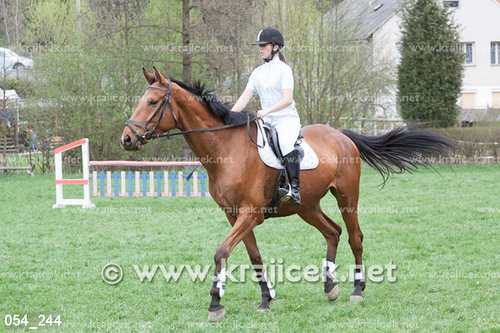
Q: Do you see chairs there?
A: No, there are no chairs.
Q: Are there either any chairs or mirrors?
A: No, there are no chairs or mirrors.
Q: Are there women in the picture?
A: Yes, there is a woman.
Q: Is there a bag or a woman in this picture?
A: Yes, there is a woman.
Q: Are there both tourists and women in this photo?
A: No, there is a woman but no tourists.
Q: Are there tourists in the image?
A: No, there are no tourists.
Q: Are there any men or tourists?
A: No, there are no tourists or men.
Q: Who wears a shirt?
A: The woman wears a shirt.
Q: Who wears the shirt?
A: The woman wears a shirt.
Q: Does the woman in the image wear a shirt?
A: Yes, the woman wears a shirt.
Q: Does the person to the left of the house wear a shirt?
A: Yes, the woman wears a shirt.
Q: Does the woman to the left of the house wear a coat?
A: No, the woman wears a shirt.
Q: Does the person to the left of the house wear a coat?
A: No, the woman wears a shirt.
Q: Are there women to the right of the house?
A: No, the woman is to the left of the house.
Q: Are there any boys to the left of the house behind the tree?
A: No, there is a woman to the left of the house.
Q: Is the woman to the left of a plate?
A: No, the woman is to the left of the house.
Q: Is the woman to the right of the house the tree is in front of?
A: No, the woman is to the left of the house.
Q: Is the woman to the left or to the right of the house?
A: The woman is to the left of the house.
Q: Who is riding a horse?
A: The woman is riding a horse.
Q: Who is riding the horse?
A: The woman is riding a horse.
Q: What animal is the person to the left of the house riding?
A: The woman is riding a horse.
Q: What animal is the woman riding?
A: The woman is riding a horse.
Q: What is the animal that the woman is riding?
A: The animal is a horse.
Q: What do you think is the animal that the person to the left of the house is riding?
A: The animal is a horse.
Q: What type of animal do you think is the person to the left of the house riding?
A: The woman is riding a horse.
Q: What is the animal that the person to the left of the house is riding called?
A: The animal is a horse.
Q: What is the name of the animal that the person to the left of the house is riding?
A: The animal is a horse.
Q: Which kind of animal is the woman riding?
A: The woman is riding a horse.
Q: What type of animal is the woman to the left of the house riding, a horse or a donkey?
A: The woman is riding a horse.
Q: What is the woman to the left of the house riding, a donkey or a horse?
A: The woman is riding a horse.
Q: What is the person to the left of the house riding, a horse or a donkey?
A: The woman is riding a horse.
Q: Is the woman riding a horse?
A: Yes, the woman is riding a horse.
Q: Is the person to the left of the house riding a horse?
A: Yes, the woman is riding a horse.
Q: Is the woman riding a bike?
A: No, the woman is riding a horse.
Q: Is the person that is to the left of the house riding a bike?
A: No, the woman is riding a horse.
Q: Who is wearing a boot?
A: The woman is wearing a boot.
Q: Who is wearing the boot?
A: The woman is wearing a boot.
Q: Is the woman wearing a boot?
A: Yes, the woman is wearing a boot.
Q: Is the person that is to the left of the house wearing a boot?
A: Yes, the woman is wearing a boot.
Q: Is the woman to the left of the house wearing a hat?
A: No, the woman is wearing a boot.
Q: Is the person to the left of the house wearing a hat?
A: No, the woman is wearing a boot.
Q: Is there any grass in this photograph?
A: Yes, there is grass.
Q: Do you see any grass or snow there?
A: Yes, there is grass.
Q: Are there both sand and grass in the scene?
A: No, there is grass but no sand.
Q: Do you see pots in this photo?
A: No, there are no pots.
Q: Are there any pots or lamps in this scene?
A: No, there are no pots or lamps.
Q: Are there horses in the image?
A: Yes, there is a horse.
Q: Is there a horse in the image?
A: Yes, there is a horse.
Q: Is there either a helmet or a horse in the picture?
A: Yes, there is a horse.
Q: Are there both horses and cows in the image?
A: No, there is a horse but no cows.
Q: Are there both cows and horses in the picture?
A: No, there is a horse but no cows.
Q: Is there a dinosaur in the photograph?
A: No, there are no dinosaurs.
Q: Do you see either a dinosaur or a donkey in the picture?
A: No, there are no dinosaurs or donkeys.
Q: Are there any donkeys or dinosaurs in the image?
A: No, there are no dinosaurs or donkeys.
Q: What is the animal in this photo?
A: The animal is a horse.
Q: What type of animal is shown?
A: The animal is a horse.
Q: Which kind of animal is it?
A: The animal is a horse.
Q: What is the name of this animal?
A: This is a horse.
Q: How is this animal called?
A: This is a horse.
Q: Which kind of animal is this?
A: This is a horse.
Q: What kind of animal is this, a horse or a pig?
A: This is a horse.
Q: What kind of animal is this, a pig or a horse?
A: This is a horse.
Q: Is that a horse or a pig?
A: That is a horse.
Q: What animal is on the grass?
A: The horse is on the grass.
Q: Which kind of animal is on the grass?
A: The animal is a horse.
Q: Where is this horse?
A: The horse is on the grass.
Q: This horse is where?
A: The horse is on the grass.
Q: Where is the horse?
A: The horse is on the grass.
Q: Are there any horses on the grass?
A: Yes, there is a horse on the grass.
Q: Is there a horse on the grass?
A: Yes, there is a horse on the grass.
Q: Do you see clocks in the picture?
A: No, there are no clocks.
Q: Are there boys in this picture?
A: No, there are no boys.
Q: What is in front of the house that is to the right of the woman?
A: The tree is in front of the house.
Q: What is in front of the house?
A: The tree is in front of the house.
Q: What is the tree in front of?
A: The tree is in front of the house.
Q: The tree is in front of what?
A: The tree is in front of the house.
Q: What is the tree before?
A: The tree is in front of the house.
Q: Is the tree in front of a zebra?
A: No, the tree is in front of the house.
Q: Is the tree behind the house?
A: No, the tree is in front of the house.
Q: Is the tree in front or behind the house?
A: The tree is in front of the house.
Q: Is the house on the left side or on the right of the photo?
A: The house is on the right of the image.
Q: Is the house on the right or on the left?
A: The house is on the right of the image.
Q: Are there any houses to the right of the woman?
A: Yes, there is a house to the right of the woman.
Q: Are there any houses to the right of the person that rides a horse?
A: Yes, there is a house to the right of the woman.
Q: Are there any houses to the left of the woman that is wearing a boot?
A: No, the house is to the right of the woman.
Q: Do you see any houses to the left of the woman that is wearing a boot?
A: No, the house is to the right of the woman.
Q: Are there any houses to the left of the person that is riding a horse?
A: No, the house is to the right of the woman.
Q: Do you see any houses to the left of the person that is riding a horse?
A: No, the house is to the right of the woman.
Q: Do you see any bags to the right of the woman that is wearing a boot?
A: No, there is a house to the right of the woman.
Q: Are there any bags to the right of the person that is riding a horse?
A: No, there is a house to the right of the woman.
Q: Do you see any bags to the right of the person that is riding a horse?
A: No, there is a house to the right of the woman.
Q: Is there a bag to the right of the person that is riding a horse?
A: No, there is a house to the right of the woman.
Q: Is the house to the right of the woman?
A: Yes, the house is to the right of the woman.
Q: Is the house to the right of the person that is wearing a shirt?
A: Yes, the house is to the right of the woman.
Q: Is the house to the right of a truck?
A: No, the house is to the right of the woman.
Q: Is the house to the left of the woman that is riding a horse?
A: No, the house is to the right of the woman.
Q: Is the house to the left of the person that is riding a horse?
A: No, the house is to the right of the woman.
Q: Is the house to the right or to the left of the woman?
A: The house is to the right of the woman.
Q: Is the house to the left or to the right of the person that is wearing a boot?
A: The house is to the right of the woman.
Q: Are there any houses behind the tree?
A: Yes, there is a house behind the tree.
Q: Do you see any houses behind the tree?
A: Yes, there is a house behind the tree.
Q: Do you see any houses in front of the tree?
A: No, the house is behind the tree.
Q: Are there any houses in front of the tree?
A: No, the house is behind the tree.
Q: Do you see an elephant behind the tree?
A: No, there is a house behind the tree.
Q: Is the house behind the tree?
A: Yes, the house is behind the tree.